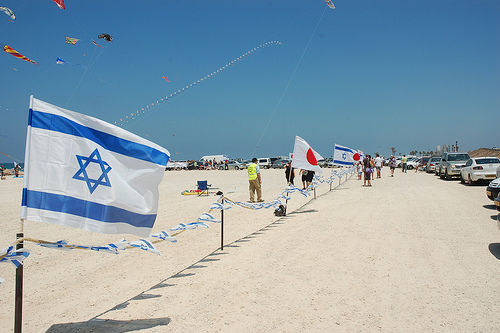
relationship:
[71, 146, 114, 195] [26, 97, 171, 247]
star on flag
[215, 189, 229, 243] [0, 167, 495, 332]
post on beach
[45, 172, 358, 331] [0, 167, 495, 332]
shadow on beach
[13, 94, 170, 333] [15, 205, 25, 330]
flag on pole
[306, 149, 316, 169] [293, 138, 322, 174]
circle on flag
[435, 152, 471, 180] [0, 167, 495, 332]
car on beach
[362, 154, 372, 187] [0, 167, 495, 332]
man on beach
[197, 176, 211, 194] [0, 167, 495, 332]
chair on beach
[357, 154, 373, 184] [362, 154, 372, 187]
man carrying man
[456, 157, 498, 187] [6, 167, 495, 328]
car parked on beach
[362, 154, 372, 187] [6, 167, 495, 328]
man walking on beach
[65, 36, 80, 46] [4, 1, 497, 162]
kite in sky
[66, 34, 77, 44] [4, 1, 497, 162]
kite in sky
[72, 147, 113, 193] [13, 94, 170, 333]
star on flag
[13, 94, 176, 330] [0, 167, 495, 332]
flag on beach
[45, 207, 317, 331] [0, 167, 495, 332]
shadow on beach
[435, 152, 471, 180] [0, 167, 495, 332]
car parked on beach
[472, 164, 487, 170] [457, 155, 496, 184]
tail light on car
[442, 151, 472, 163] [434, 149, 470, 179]
windshield of car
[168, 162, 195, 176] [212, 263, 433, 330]
suv on beach